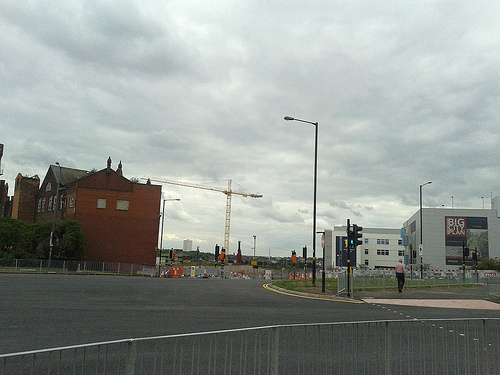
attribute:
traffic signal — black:
[344, 218, 362, 300]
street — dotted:
[76, 272, 259, 364]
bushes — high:
[2, 218, 114, 271]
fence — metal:
[1, 259, 167, 274]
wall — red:
[71, 183, 161, 267]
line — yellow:
[260, 281, 365, 305]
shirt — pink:
[393, 261, 405, 273]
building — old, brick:
[0, 163, 161, 268]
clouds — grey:
[197, 36, 407, 96]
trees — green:
[0, 216, 86, 270]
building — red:
[63, 155, 162, 272]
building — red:
[33, 164, 89, 220]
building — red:
[0, 172, 39, 221]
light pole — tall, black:
[289, 122, 356, 270]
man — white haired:
[393, 258, 409, 294]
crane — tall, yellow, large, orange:
[137, 175, 262, 263]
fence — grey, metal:
[5, 316, 497, 373]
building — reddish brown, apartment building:
[7, 156, 167, 284]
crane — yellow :
[135, 167, 265, 272]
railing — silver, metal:
[0, 318, 499, 373]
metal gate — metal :
[4, 315, 496, 372]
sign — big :
[444, 211, 491, 273]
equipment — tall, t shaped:
[160, 175, 264, 250]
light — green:
[338, 208, 390, 257]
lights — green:
[344, 223, 360, 245]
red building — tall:
[47, 166, 157, 267]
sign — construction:
[285, 245, 300, 266]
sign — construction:
[247, 251, 261, 270]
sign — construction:
[213, 243, 228, 263]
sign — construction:
[165, 246, 176, 260]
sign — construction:
[160, 262, 185, 277]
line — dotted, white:
[357, 300, 493, 349]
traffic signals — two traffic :
[352, 224, 363, 270]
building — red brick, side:
[0, 157, 161, 276]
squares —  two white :
[96, 195, 130, 209]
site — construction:
[181, 228, 471, 293]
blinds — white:
[93, 195, 114, 213]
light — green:
[345, 236, 360, 247]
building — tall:
[177, 237, 200, 254]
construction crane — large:
[148, 173, 268, 258]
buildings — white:
[325, 208, 494, 289]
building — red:
[36, 172, 186, 274]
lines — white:
[374, 300, 420, 323]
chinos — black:
[387, 270, 417, 297]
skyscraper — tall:
[173, 235, 202, 265]